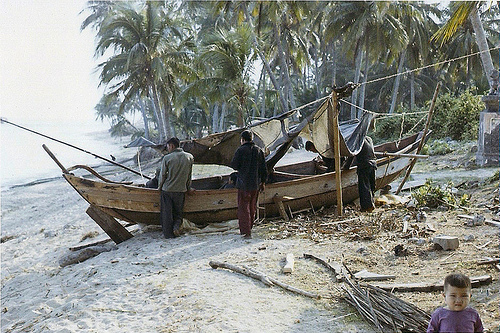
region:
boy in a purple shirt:
[425, 275, 490, 331]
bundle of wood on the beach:
[323, 277, 436, 330]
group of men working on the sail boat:
[143, 129, 380, 237]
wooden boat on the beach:
[43, 112, 433, 238]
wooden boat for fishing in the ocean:
[41, 81, 447, 241]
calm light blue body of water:
[0, 114, 131, 189]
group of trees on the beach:
[80, 0, 498, 153]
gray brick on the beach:
[429, 233, 457, 250]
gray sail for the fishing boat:
[130, 89, 380, 176]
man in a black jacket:
[231, 128, 268, 237]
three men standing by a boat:
[141, 95, 408, 228]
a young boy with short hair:
[428, 259, 492, 332]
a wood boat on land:
[52, 94, 441, 244]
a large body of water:
[0, 104, 150, 197]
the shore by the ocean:
[6, 114, 142, 225]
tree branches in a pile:
[319, 272, 430, 332]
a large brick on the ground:
[426, 229, 477, 258]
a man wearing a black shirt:
[234, 109, 275, 201]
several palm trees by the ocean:
[55, 0, 455, 188]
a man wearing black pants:
[152, 135, 199, 238]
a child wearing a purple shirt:
[414, 265, 486, 330]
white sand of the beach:
[48, 282, 167, 324]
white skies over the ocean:
[10, 0, 73, 87]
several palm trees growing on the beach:
[89, 8, 409, 88]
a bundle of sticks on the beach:
[331, 261, 420, 323]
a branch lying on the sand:
[195, 260, 320, 308]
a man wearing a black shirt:
[217, 123, 277, 238]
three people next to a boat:
[156, 125, 401, 253]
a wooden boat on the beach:
[41, 150, 441, 225]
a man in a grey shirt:
[153, 135, 198, 242]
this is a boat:
[68, 170, 143, 225]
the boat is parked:
[95, 180, 154, 207]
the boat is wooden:
[107, 182, 144, 214]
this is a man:
[229, 119, 273, 228]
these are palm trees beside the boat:
[118, 7, 407, 69]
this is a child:
[434, 271, 483, 331]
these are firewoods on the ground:
[358, 282, 400, 317]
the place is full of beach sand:
[135, 247, 181, 330]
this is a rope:
[412, 55, 452, 82]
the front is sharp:
[59, 159, 111, 211]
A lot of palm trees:
[90, 3, 497, 155]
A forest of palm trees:
[92, 3, 499, 154]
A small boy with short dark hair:
[430, 271, 486, 331]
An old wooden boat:
[47, 91, 427, 237]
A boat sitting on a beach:
[38, 90, 434, 238]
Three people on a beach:
[155, 133, 380, 234]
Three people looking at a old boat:
[155, 128, 381, 237]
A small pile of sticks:
[342, 271, 430, 331]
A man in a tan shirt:
[154, 137, 195, 236]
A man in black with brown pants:
[230, 132, 269, 234]